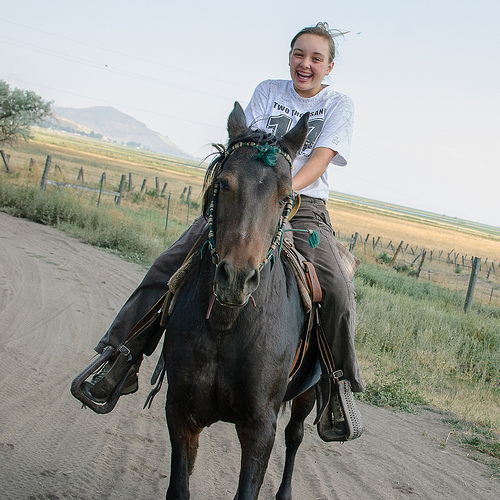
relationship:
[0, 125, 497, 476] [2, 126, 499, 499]
grass on ground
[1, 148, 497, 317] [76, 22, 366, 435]
fence behind girl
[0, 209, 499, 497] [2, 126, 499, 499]
dirt on ground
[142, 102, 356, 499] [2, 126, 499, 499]
horse on ground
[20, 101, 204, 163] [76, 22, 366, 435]
mountain behind girl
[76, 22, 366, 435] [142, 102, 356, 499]
girl riding a horse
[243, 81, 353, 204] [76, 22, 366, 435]
shirt on girl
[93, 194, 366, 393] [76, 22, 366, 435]
pants on girl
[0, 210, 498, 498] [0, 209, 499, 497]
tracks in dirt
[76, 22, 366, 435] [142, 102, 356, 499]
girl on horse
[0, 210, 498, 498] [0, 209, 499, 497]
tracks on dirt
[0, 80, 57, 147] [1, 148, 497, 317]
tree near fence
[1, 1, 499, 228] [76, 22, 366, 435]
sky above girl